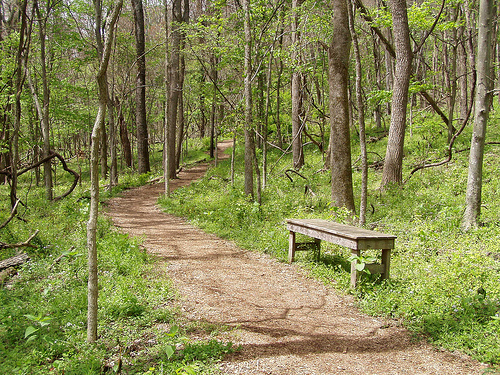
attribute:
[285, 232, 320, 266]
bench — wooden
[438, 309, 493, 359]
grass — bright, green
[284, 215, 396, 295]
bench — wooden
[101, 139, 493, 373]
path — wide, thin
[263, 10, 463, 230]
trees — many, thin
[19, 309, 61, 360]
plant — green, leafy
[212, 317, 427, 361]
shadow — wide, dark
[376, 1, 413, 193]
trunk — brown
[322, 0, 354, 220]
trunk — brown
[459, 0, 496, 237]
trunk — brown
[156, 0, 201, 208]
trunk — brown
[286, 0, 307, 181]
trunk — brown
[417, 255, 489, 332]
grass — bright green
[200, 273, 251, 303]
dirt — brown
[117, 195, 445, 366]
path — walkway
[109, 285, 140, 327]
grass — bright green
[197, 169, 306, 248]
grass patch — bright green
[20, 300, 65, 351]
grass — bright green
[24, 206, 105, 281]
grass — green, bright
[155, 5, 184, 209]
tree — tall